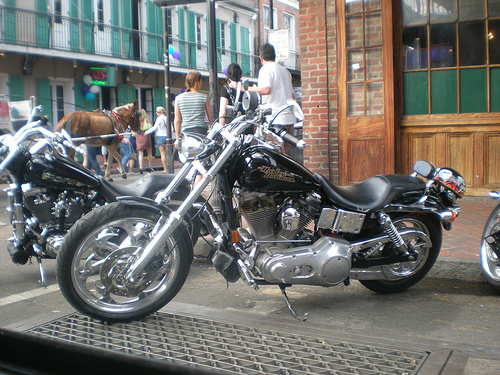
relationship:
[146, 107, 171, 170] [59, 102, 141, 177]
woman guiding horse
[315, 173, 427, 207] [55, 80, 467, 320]
seat of harley davidson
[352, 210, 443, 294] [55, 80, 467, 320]
black tire of harley davidson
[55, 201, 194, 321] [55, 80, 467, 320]
black tire of harley davidson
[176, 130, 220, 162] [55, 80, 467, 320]
headlight of harley davidson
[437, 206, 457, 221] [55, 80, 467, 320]
taillight of harley davidson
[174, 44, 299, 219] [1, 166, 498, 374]
people on street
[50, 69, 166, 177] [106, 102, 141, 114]
horse with mane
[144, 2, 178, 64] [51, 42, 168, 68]
door on floor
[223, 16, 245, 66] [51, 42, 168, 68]
door on floor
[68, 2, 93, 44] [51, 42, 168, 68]
door on floor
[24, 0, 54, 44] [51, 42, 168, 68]
door on floor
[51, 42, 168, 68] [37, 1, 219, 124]
floor of hotel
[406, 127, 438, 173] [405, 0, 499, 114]
panel below window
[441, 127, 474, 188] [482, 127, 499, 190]
panel below panel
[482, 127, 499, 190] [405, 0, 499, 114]
panel below window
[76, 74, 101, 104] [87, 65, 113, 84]
balloons next to neon sign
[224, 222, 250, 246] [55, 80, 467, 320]
reflector on harley davidson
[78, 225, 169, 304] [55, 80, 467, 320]
rim on harley davidson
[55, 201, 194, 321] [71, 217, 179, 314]
black tire outside rim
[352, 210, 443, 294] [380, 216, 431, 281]
black tire outside rim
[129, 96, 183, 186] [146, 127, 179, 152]
person wearing shorts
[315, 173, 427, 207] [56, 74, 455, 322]
seat on motorbike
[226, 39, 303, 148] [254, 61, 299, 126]
man wearing shirt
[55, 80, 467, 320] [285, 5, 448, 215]
harley davidson parked in front of building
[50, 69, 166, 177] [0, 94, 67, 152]
horse attached to buggy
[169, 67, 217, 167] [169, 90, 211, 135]
woman in striped shirt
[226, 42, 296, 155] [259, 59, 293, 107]
man in shirt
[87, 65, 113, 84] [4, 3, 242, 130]
neon sign on front of building